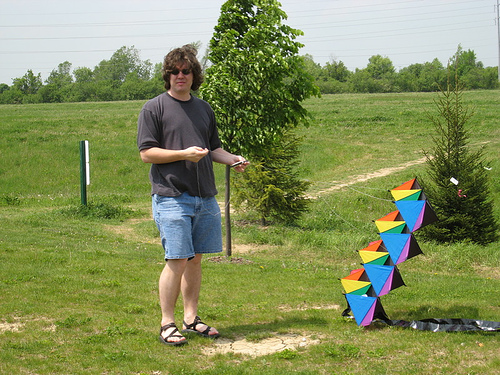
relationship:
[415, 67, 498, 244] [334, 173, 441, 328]
tree near kite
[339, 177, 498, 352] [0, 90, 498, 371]
kite on ground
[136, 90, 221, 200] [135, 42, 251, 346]
black shirt on he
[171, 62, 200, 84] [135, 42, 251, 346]
glasses on he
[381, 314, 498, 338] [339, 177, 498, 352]
black tails on kite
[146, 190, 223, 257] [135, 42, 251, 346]
shorts on he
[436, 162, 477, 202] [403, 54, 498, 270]
tag on tree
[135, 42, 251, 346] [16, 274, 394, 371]
he in field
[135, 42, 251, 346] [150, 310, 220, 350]
he in sandals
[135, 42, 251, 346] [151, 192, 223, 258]
he in shorts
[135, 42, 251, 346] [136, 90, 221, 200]
he in black shirt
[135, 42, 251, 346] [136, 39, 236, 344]
he in t-shirt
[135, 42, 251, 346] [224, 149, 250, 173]
he holding phone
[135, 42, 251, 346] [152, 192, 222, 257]
he wears denim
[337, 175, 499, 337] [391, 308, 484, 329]
kite has tail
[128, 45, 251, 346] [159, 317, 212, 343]
he wears sandals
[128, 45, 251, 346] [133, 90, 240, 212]
he wearing gray shirt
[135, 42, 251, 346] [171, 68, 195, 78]
he wearing glasses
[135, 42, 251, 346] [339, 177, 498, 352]
he holds kite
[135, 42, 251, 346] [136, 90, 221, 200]
he wears black shirt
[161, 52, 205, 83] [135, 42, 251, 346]
hair on he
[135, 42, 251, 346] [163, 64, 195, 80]
he wear glasses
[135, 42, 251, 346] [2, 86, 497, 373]
he stands on grass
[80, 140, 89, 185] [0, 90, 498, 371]
sign on ground